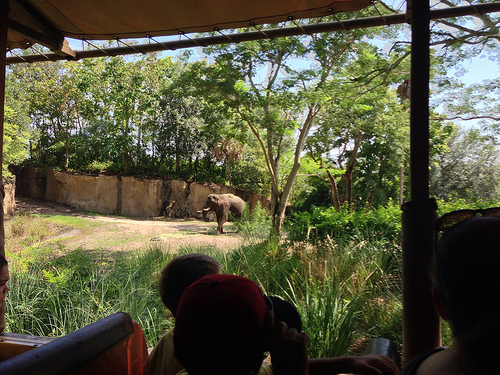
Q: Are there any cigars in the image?
A: No, there are no cigars.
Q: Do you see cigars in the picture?
A: No, there are no cigars.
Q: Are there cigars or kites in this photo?
A: No, there are no cigars or kites.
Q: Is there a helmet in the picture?
A: No, there are no helmets.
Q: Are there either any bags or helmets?
A: No, there are no helmets or bags.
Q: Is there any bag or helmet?
A: No, there are no helmets or bags.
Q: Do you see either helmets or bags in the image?
A: No, there are no helmets or bags.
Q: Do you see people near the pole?
A: Yes, there is a person near the pole.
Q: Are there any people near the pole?
A: Yes, there is a person near the pole.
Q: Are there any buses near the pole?
A: No, there is a person near the pole.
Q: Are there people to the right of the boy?
A: Yes, there is a person to the right of the boy.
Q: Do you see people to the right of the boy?
A: Yes, there is a person to the right of the boy.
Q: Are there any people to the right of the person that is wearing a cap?
A: Yes, there is a person to the right of the boy.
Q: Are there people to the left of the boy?
A: No, the person is to the right of the boy.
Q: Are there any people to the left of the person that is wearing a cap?
A: No, the person is to the right of the boy.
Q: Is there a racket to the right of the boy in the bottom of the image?
A: No, there is a person to the right of the boy.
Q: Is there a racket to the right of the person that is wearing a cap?
A: No, there is a person to the right of the boy.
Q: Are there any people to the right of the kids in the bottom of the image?
A: Yes, there is a person to the right of the children.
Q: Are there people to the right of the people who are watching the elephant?
A: Yes, there is a person to the right of the children.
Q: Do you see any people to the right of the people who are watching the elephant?
A: Yes, there is a person to the right of the children.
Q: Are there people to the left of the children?
A: No, the person is to the right of the children.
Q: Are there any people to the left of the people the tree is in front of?
A: No, the person is to the right of the children.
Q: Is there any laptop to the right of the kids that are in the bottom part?
A: No, there is a person to the right of the kids.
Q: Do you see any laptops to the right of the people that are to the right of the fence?
A: No, there is a person to the right of the kids.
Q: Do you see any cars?
A: No, there are no cars.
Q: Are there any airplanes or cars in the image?
A: No, there are no cars or airplanes.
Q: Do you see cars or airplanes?
A: No, there are no cars or airplanes.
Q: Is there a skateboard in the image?
A: No, there are no skateboards.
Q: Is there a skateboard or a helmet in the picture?
A: No, there are no skateboards or helmets.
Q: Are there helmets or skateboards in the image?
A: No, there are no skateboards or helmets.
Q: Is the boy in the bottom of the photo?
A: Yes, the boy is in the bottom of the image.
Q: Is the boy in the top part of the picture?
A: No, the boy is in the bottom of the image.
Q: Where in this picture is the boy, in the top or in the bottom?
A: The boy is in the bottom of the image.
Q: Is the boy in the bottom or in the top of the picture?
A: The boy is in the bottom of the image.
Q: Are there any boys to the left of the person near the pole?
A: Yes, there is a boy to the left of the person.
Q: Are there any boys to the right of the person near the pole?
A: No, the boy is to the left of the person.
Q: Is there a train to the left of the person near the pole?
A: No, there is a boy to the left of the person.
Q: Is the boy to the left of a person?
A: Yes, the boy is to the left of a person.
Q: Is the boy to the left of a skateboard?
A: No, the boy is to the left of a person.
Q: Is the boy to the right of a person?
A: No, the boy is to the left of a person.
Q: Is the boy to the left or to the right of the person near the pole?
A: The boy is to the left of the person.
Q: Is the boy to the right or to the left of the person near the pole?
A: The boy is to the left of the person.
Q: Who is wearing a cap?
A: The boy is wearing a cap.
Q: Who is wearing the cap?
A: The boy is wearing a cap.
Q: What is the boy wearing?
A: The boy is wearing a cap.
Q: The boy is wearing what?
A: The boy is wearing a cap.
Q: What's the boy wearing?
A: The boy is wearing a cap.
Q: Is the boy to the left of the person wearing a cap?
A: Yes, the boy is wearing a cap.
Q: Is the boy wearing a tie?
A: No, the boy is wearing a cap.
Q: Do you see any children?
A: Yes, there are children.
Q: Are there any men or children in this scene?
A: Yes, there are children.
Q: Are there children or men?
A: Yes, there are children.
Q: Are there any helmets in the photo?
A: No, there are no helmets.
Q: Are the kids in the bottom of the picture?
A: Yes, the kids are in the bottom of the image.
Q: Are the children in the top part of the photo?
A: No, the children are in the bottom of the image.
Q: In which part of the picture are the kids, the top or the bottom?
A: The kids are in the bottom of the image.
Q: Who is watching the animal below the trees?
A: The children are watching the elephant.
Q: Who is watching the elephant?
A: The children are watching the elephant.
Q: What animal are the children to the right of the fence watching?
A: The kids are watching the elephant.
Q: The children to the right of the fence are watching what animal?
A: The kids are watching the elephant.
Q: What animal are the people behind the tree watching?
A: The kids are watching the elephant.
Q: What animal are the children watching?
A: The kids are watching the elephant.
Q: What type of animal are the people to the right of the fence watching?
A: The children are watching the elephant.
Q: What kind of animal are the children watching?
A: The children are watching the elephant.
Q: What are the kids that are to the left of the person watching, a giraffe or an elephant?
A: The children are watching an elephant.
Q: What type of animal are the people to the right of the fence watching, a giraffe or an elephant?
A: The children are watching an elephant.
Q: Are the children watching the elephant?
A: Yes, the children are watching the elephant.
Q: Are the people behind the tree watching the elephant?
A: Yes, the children are watching the elephant.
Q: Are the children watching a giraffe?
A: No, the children are watching the elephant.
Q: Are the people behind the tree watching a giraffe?
A: No, the children are watching the elephant.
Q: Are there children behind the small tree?
A: Yes, there are children behind the tree.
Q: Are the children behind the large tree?
A: Yes, the children are behind the tree.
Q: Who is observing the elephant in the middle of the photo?
A: The children are observing the elephant.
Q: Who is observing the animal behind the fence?
A: The children are observing the elephant.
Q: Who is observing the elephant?
A: The children are observing the elephant.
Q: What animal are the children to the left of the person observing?
A: The children are observing the elephant.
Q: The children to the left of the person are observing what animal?
A: The children are observing the elephant.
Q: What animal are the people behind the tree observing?
A: The children are observing the elephant.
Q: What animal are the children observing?
A: The children are observing the elephant.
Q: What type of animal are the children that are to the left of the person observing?
A: The children are observing the elephant.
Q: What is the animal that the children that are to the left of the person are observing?
A: The animal is an elephant.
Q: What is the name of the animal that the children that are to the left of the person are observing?
A: The animal is an elephant.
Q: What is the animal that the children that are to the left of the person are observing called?
A: The animal is an elephant.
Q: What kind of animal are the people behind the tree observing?
A: The children are observing the elephant.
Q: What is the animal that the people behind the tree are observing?
A: The animal is an elephant.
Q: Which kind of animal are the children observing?
A: The children are observing the elephant.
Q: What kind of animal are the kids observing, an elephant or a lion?
A: The kids are observing an elephant.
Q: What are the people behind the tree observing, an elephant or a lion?
A: The kids are observing an elephant.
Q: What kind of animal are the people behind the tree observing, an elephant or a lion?
A: The kids are observing an elephant.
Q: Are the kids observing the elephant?
A: Yes, the kids are observing the elephant.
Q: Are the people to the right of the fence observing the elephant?
A: Yes, the kids are observing the elephant.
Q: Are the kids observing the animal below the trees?
A: Yes, the kids are observing the elephant.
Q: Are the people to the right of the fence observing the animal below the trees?
A: Yes, the kids are observing the elephant.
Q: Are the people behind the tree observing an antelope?
A: No, the children are observing the elephant.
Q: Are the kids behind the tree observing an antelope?
A: No, the children are observing the elephant.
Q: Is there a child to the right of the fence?
A: Yes, there are children to the right of the fence.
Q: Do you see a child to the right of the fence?
A: Yes, there are children to the right of the fence.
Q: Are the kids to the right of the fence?
A: Yes, the kids are to the right of the fence.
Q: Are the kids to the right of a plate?
A: No, the kids are to the right of the fence.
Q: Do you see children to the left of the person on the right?
A: Yes, there are children to the left of the person.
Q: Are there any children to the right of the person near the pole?
A: No, the children are to the left of the person.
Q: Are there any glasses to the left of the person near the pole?
A: No, there are children to the left of the person.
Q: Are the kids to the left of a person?
A: Yes, the kids are to the left of a person.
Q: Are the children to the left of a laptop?
A: No, the children are to the left of a person.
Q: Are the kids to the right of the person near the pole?
A: No, the kids are to the left of the person.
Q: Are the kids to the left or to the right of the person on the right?
A: The kids are to the left of the person.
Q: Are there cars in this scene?
A: No, there are no cars.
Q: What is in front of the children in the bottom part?
A: The tree is in front of the children.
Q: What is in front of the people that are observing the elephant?
A: The tree is in front of the children.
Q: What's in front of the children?
A: The tree is in front of the children.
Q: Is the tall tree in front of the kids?
A: Yes, the tree is in front of the kids.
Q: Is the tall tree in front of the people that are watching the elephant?
A: Yes, the tree is in front of the kids.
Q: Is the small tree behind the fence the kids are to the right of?
A: Yes, the tree is behind the fence.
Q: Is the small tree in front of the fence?
A: No, the tree is behind the fence.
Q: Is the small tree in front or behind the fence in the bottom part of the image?
A: The tree is behind the fence.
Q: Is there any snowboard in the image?
A: No, there are no snowboards.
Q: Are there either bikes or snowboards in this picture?
A: No, there are no snowboards or bikes.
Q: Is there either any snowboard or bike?
A: No, there are no snowboards or bikes.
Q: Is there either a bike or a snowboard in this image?
A: No, there are no snowboards or bikes.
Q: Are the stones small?
A: Yes, the stones are small.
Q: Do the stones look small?
A: Yes, the stones are small.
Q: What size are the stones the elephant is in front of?
A: The stones are small.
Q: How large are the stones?
A: The stones are small.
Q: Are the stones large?
A: No, the stones are small.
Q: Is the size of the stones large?
A: No, the stones are small.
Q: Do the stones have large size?
A: No, the stones are small.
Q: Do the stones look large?
A: No, the stones are small.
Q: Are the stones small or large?
A: The stones are small.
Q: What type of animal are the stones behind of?
A: The stones are behind the elephant.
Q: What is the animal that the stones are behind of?
A: The animal is an elephant.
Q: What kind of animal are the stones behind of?
A: The stones are behind the elephant.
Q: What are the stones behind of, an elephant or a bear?
A: The stones are behind an elephant.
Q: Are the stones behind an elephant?
A: Yes, the stones are behind an elephant.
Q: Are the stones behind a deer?
A: No, the stones are behind an elephant.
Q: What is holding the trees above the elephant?
A: The stones are holding the trees.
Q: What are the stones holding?
A: The stones are holding the trees.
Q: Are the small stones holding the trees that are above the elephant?
A: Yes, the stones are holding the trees.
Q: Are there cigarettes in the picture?
A: No, there are no cigarettes.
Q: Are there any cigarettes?
A: No, there are no cigarettes.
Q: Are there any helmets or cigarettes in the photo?
A: No, there are no cigarettes or helmets.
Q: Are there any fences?
A: Yes, there is a fence.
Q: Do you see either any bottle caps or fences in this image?
A: Yes, there is a fence.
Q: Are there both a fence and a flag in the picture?
A: No, there is a fence but no flags.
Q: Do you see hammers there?
A: No, there are no hammers.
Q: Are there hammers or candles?
A: No, there are no hammers or candles.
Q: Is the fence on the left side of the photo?
A: Yes, the fence is on the left of the image.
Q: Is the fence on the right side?
A: No, the fence is on the left of the image.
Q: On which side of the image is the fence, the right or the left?
A: The fence is on the left of the image.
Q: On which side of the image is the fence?
A: The fence is on the left of the image.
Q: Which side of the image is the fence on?
A: The fence is on the left of the image.